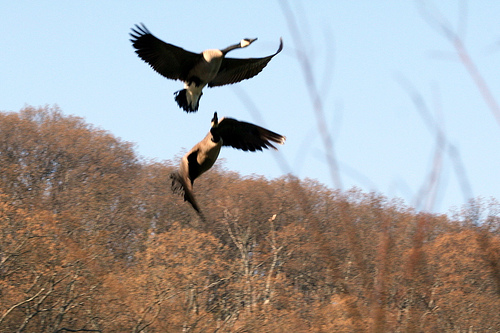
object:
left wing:
[207, 37, 282, 88]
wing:
[166, 149, 206, 223]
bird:
[168, 111, 287, 224]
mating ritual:
[127, 21, 286, 227]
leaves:
[1, 109, 111, 180]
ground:
[368, 156, 403, 185]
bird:
[271, 214, 278, 222]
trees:
[419, 226, 498, 332]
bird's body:
[188, 138, 219, 181]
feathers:
[173, 84, 201, 113]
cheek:
[240, 39, 250, 47]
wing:
[126, 23, 199, 82]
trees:
[0, 234, 100, 333]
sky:
[5, 3, 464, 39]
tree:
[218, 175, 263, 333]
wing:
[216, 116, 286, 152]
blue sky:
[1, 0, 500, 258]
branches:
[36, 151, 67, 211]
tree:
[0, 105, 142, 277]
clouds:
[59, 21, 101, 96]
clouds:
[71, 28, 105, 88]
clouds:
[411, 49, 465, 132]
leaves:
[0, 188, 121, 331]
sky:
[1, 0, 498, 114]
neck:
[221, 42, 240, 57]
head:
[236, 37, 259, 48]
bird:
[127, 20, 283, 114]